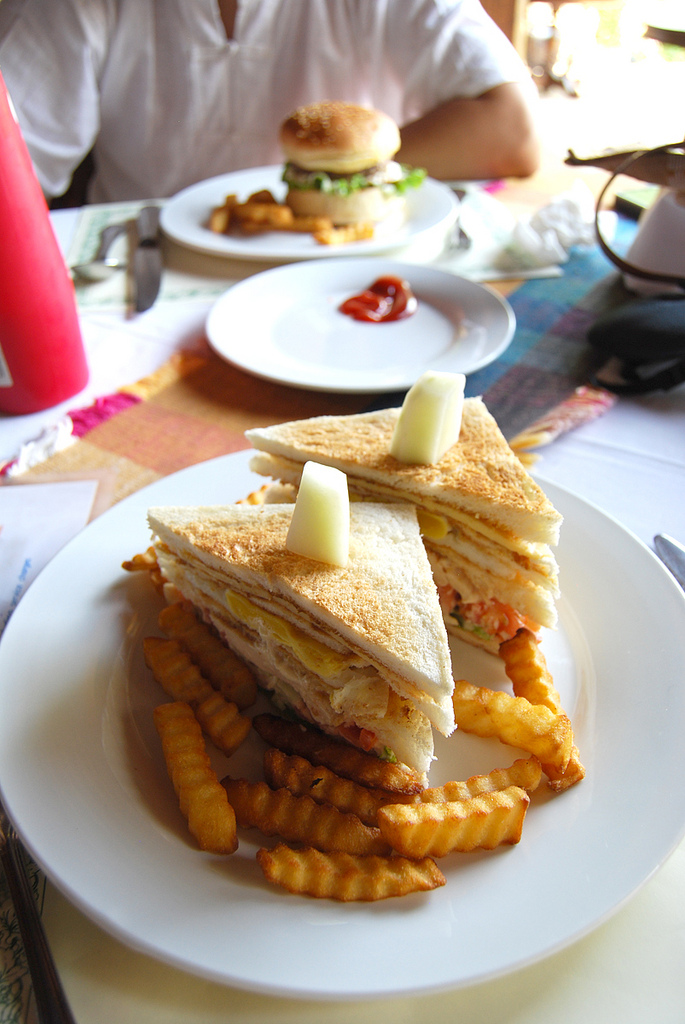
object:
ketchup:
[352, 275, 405, 324]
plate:
[265, 326, 461, 373]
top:
[55, 14, 173, 118]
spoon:
[80, 220, 116, 283]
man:
[0, 6, 528, 195]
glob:
[363, 275, 421, 310]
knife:
[136, 220, 151, 300]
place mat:
[185, 263, 227, 302]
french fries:
[210, 184, 293, 225]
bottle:
[0, 66, 89, 420]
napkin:
[478, 212, 531, 276]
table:
[593, 451, 655, 478]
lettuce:
[283, 168, 331, 188]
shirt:
[31, 72, 153, 159]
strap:
[589, 231, 627, 259]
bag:
[593, 149, 679, 286]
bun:
[279, 85, 396, 236]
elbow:
[426, 83, 530, 173]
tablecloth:
[526, 302, 564, 381]